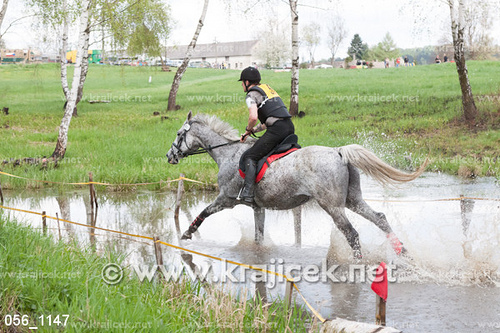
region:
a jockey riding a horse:
[126, 42, 428, 299]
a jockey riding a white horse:
[157, 50, 426, 288]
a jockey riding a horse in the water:
[163, 52, 423, 277]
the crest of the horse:
[198, 112, 227, 139]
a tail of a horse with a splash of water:
[333, 132, 440, 199]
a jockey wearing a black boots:
[227, 55, 301, 213]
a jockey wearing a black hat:
[236, 64, 268, 91]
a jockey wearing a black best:
[244, 85, 294, 128]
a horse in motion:
[130, 105, 445, 270]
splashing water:
[397, 183, 484, 318]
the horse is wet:
[154, 46, 419, 331]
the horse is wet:
[183, 135, 368, 322]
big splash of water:
[405, 208, 497, 294]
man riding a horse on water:
[169, 64, 424, 264]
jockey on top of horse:
[236, 50, 308, 227]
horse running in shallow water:
[145, 102, 434, 287]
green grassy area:
[13, 242, 152, 332]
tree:
[53, 7, 96, 174]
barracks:
[102, 37, 279, 79]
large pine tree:
[347, 25, 369, 64]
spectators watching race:
[372, 51, 457, 69]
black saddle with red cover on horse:
[227, 126, 309, 186]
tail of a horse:
[371, 167, 375, 179]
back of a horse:
[301, 162, 325, 183]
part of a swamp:
[455, 186, 492, 227]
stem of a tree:
[295, 49, 299, 100]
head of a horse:
[172, 112, 197, 165]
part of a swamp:
[373, 262, 409, 302]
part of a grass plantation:
[366, 81, 390, 118]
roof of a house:
[192, 20, 221, 44]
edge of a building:
[230, 53, 255, 65]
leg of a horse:
[200, 197, 218, 239]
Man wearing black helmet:
[238, 61, 265, 85]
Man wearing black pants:
[244, 140, 268, 163]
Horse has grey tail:
[336, 137, 431, 189]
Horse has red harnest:
[258, 160, 268, 180]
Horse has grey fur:
[288, 166, 330, 188]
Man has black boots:
[233, 171, 259, 212]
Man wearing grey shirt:
[247, 89, 264, 103]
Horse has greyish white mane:
[193, 113, 239, 140]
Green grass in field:
[97, 119, 147, 159]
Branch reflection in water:
[99, 206, 168, 228]